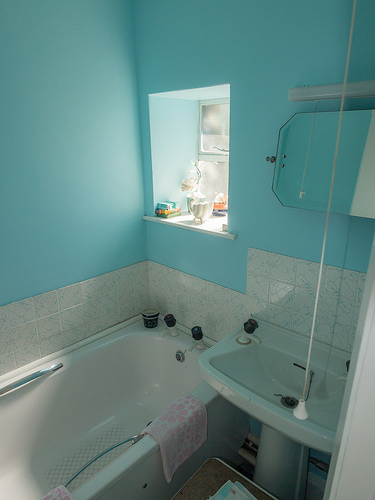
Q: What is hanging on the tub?
A: Towels.